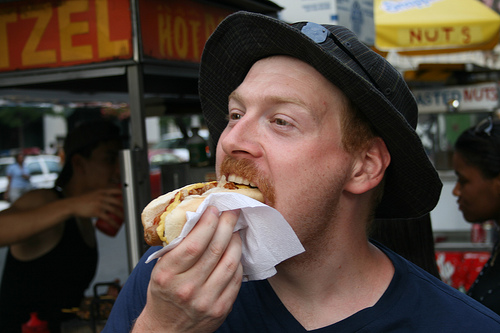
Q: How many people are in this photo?
A: One.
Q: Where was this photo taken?
A: At a hotdog stand.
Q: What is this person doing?
A: Eating a hot dog.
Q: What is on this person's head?
A: A hat.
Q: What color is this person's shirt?
A: Blue.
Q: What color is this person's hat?
A: Black.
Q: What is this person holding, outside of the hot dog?
A: A napkin.